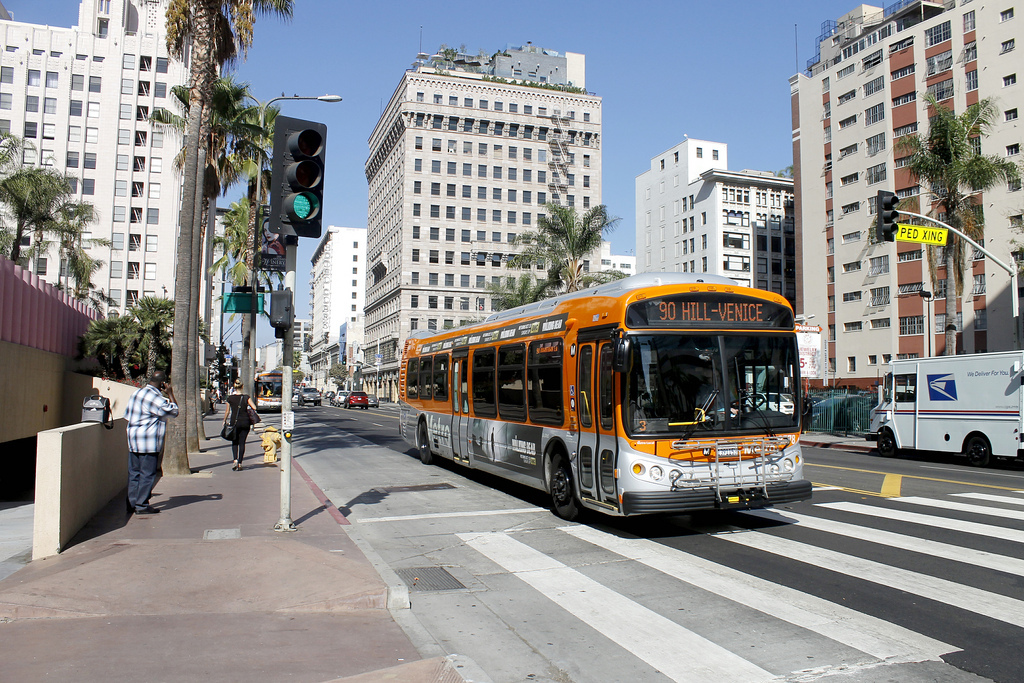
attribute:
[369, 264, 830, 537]
bus — orange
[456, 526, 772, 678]
line — white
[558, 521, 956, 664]
line — white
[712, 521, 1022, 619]
line — white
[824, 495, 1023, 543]
line — white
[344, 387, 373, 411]
car — red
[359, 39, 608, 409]
building — LARGE, WHITE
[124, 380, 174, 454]
shirt — blue and white